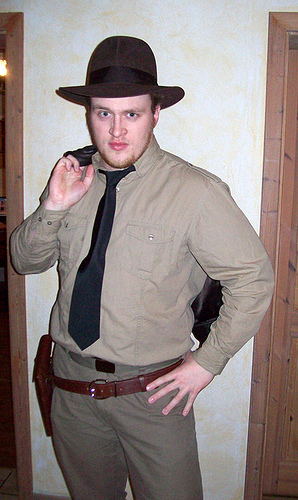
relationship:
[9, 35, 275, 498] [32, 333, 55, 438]
man wearing holster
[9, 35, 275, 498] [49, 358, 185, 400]
man wearing belt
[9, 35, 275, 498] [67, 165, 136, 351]
man wearing tie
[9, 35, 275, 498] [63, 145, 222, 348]
man holding jacket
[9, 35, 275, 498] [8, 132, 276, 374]
man wearing shirt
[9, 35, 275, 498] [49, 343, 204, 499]
man wearing pants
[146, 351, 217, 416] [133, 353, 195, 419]
hand at hip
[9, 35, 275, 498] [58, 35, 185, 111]
man wearing cowboy hat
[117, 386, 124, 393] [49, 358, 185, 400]
hole in front of belt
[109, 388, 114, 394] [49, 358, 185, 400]
hole in front of belt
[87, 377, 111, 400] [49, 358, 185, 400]
buckle on front of belt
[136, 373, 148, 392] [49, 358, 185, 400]
loop on front of belt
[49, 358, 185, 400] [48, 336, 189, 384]
belt worn on waist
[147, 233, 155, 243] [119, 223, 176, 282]
button on front of pocket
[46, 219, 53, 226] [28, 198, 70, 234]
button on front of cuff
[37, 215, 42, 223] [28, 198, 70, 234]
button on front of cuff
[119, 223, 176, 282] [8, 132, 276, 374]
pocket on front of shirt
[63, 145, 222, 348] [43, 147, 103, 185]
jacket over shoulder